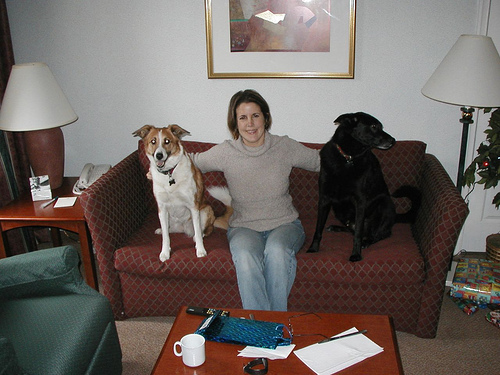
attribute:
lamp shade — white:
[0, 63, 79, 131]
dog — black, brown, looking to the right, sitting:
[306, 112, 423, 263]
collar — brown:
[332, 141, 369, 164]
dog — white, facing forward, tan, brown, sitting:
[132, 125, 226, 262]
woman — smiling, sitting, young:
[188, 90, 322, 311]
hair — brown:
[227, 90, 272, 141]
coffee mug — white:
[174, 333, 207, 366]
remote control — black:
[185, 304, 230, 320]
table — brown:
[150, 304, 405, 374]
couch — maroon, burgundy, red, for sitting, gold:
[79, 139, 470, 337]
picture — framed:
[204, 1, 356, 79]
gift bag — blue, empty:
[195, 309, 293, 349]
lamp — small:
[1, 62, 79, 192]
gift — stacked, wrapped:
[450, 255, 500, 305]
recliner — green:
[1, 244, 123, 374]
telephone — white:
[73, 163, 112, 195]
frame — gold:
[204, 1, 358, 80]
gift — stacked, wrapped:
[447, 290, 480, 316]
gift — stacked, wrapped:
[485, 309, 500, 328]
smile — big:
[244, 128, 257, 135]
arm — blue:
[0, 245, 82, 298]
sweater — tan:
[188, 130, 322, 232]